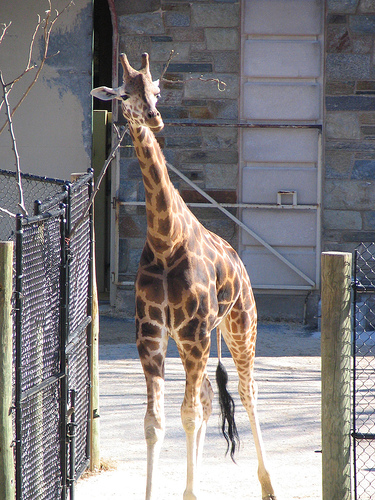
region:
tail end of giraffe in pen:
[215, 347, 235, 461]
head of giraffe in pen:
[89, 43, 169, 145]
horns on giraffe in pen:
[115, 48, 155, 71]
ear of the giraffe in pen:
[87, 81, 118, 101]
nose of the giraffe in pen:
[145, 105, 162, 121]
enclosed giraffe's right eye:
[120, 90, 130, 103]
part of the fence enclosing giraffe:
[319, 235, 372, 349]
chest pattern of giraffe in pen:
[140, 254, 194, 312]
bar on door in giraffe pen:
[240, 190, 321, 223]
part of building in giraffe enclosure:
[337, 99, 373, 158]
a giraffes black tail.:
[215, 327, 245, 465]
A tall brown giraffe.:
[89, 50, 275, 498]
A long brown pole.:
[320, 249, 353, 497]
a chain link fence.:
[0, 168, 94, 498]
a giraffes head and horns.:
[89, 50, 164, 132]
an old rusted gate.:
[110, 116, 322, 292]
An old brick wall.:
[112, 2, 373, 284]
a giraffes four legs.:
[134, 321, 276, 497]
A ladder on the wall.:
[238, 2, 324, 291]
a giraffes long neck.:
[128, 124, 201, 253]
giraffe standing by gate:
[81, 47, 312, 498]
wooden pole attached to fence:
[310, 247, 366, 498]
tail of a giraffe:
[212, 335, 242, 475]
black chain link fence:
[5, 167, 97, 498]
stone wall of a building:
[333, 8, 369, 227]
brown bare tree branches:
[2, 5, 78, 196]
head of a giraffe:
[87, 48, 178, 138]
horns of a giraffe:
[116, 51, 156, 72]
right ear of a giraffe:
[88, 85, 117, 98]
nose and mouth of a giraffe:
[140, 110, 172, 136]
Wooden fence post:
[311, 245, 373, 497]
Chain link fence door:
[26, 222, 69, 464]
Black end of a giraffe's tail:
[214, 360, 241, 465]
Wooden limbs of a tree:
[0, 9, 71, 199]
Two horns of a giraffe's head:
[107, 45, 158, 76]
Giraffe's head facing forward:
[87, 49, 176, 140]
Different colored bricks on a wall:
[174, 26, 236, 164]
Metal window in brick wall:
[242, 126, 320, 289]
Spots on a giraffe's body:
[140, 242, 253, 333]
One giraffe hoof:
[253, 479, 283, 498]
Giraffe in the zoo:
[87, 42, 284, 498]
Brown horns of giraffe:
[116, 48, 155, 76]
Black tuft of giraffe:
[210, 358, 247, 468]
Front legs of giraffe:
[130, 330, 207, 497]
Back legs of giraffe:
[198, 346, 278, 497]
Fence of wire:
[309, 229, 371, 499]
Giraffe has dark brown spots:
[77, 48, 281, 499]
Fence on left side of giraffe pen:
[9, 154, 110, 495]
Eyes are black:
[117, 90, 163, 102]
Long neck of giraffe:
[125, 127, 201, 229]